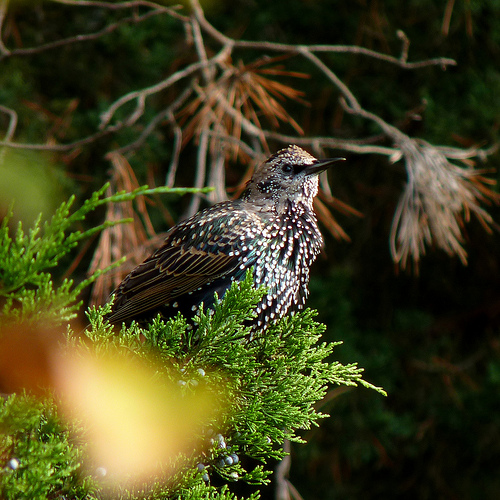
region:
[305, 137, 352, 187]
the beak is black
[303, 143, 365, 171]
the beak is pointy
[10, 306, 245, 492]
the picture is blurry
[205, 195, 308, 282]
the fur has dots on it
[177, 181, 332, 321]
the dots are white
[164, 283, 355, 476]
the leaves are green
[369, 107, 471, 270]
the flower is white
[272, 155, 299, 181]
the eye is open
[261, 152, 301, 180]
the eye is black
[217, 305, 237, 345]
part of a feather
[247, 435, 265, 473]
edge of a tree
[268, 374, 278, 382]
part of a branch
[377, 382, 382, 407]
part of a branch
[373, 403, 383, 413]
part of a branch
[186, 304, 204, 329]
part of a feather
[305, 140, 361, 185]
beak of the bird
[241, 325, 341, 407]
leaves under the bird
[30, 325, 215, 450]
blurry thing in foreground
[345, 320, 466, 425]
leaves in the background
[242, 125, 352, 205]
head of the bird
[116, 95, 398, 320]
one bird sitting on tree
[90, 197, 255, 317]
feathers on side of bird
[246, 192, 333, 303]
front of the bird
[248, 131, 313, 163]
top of the bird's head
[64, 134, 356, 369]
european [or, now, 'common'] starling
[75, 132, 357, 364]
certainly UNcommon once in the US, the european starling was introduced here by a shakespearean who wanted americans to be able to know all of the birds in shakespeare. with the european starling, he succeeded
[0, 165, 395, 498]
sitting in the cedar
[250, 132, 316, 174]
juvenile brown patch on head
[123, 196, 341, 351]
white-spotted body feathers are formative feathers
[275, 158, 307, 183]
eye stripe is dark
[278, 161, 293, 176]
and the eye is dark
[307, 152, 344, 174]
A long black beak of a bird.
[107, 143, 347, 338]
A black, white and brown bird with black beak.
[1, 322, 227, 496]
A large orange and white blurry spot.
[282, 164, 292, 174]
Small black round right eye of a bird.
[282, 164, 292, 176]
A round black bird eye.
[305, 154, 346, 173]
A black bird beak.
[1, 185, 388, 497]
Green vibrant leaves on a bush a bird is sitting in.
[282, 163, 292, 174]
Small black bird eye with white reflection.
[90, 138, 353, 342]
Birds in foliage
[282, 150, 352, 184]
Long beak of bird